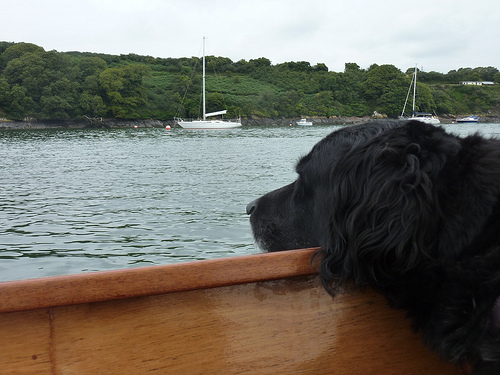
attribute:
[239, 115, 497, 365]
dog — resting, black, overlooking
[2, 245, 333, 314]
ledge — wooden, brown, wood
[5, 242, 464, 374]
boat — white, sailboat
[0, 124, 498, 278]
water — choppy, calm, green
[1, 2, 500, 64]
sky — cloudy, blue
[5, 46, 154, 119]
trees — forest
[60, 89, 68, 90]
leaves — green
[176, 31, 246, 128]
boat — docked, white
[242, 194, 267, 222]
nose — black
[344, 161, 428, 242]
fur — black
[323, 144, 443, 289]
ears — flat, black